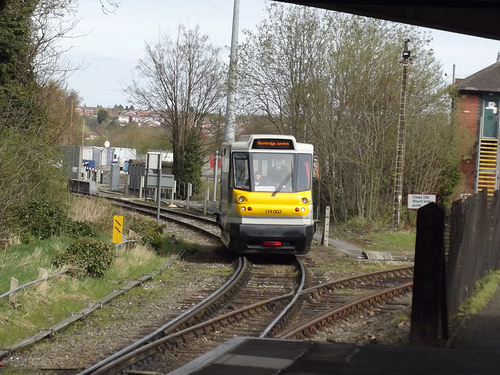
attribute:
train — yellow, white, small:
[199, 141, 324, 260]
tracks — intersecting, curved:
[230, 254, 321, 343]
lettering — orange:
[252, 135, 291, 153]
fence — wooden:
[386, 196, 498, 355]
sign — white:
[402, 191, 444, 213]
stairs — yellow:
[473, 135, 497, 207]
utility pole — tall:
[387, 38, 413, 222]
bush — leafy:
[429, 168, 461, 198]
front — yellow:
[234, 182, 324, 220]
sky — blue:
[78, 27, 149, 69]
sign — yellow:
[107, 198, 127, 270]